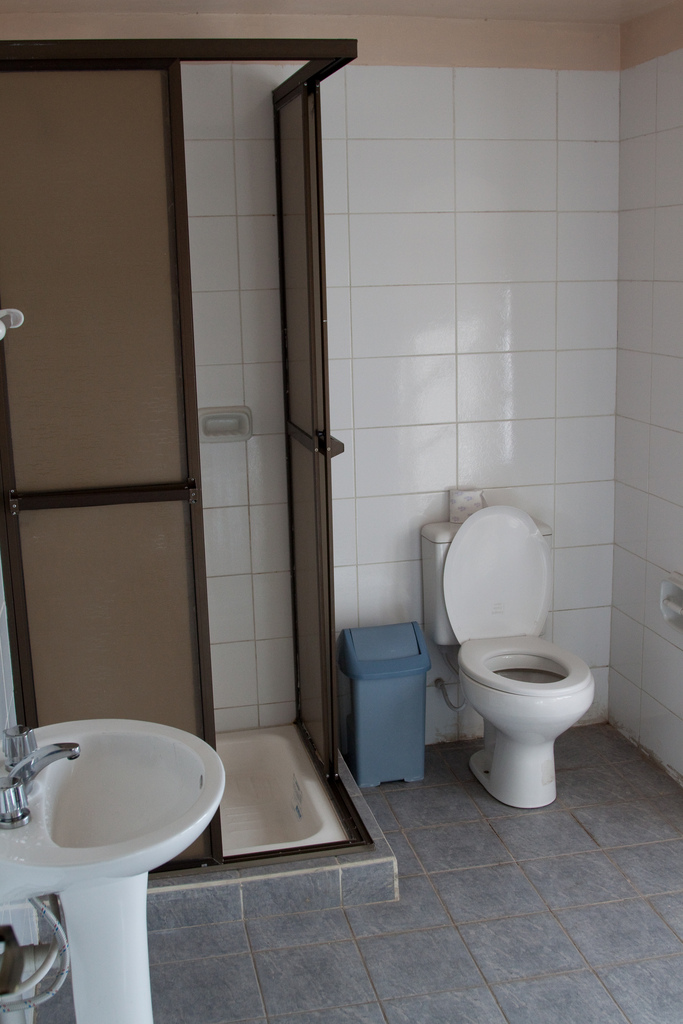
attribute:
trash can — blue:
[331, 616, 437, 790]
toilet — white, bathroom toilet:
[413, 498, 599, 814]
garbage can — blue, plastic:
[336, 616, 436, 793]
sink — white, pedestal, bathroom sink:
[2, 712, 231, 1022]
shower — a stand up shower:
[3, 34, 403, 938]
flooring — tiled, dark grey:
[2, 714, 680, 1021]